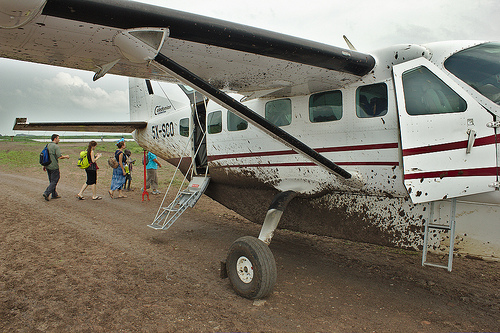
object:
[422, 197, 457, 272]
ladder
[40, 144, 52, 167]
backpack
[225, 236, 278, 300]
tire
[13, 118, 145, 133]
fin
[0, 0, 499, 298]
airplane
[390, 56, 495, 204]
door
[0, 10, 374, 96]
wing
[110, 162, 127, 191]
dress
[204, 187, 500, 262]
bottom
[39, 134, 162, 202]
people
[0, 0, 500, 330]
plane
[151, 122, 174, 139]
letter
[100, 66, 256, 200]
back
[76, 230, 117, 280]
ground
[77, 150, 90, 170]
backpack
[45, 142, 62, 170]
shirt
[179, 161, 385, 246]
mud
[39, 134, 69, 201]
man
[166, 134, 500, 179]
line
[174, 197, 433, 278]
side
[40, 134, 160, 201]
group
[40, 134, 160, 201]
tourist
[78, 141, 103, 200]
woman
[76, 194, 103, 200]
feet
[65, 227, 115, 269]
dirt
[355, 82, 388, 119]
window